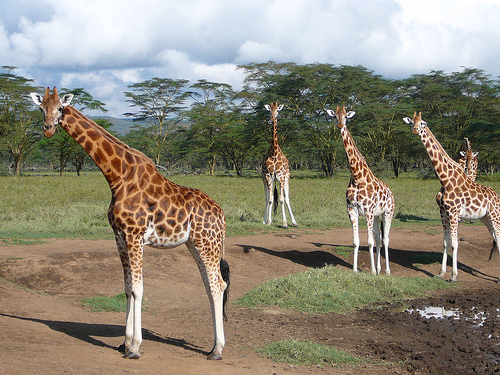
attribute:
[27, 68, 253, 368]
giraffe — brown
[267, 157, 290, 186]
spots — brown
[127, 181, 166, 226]
spots — brown 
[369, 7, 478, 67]
cloud — white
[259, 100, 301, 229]
giraffe — brown, tan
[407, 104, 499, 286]
spotted giraffe — tan, brown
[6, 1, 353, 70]
cloud — white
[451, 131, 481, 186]
giraffe — tan, brown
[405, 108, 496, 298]
giraffe — brown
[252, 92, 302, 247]
giraffe — brown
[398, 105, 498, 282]
giraffe — tan, brown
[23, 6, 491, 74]
clouds — white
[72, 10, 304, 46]
sky — blue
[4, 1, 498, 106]
clouds — white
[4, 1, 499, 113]
sky — clouds, blue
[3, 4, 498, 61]
sky — blue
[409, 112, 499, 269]
giraffe — tall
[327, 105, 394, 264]
giraffe — tall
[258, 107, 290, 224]
giraffe — tall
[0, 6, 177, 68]
clouds — white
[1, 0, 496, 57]
sky — blue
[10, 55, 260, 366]
giraffe — tan, brown, spotted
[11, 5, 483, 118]
clouds — white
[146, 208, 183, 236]
spots — brown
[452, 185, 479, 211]
spots — brown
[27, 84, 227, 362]
giraffe — tan and brown, spotted, tan and brown spotted, tall